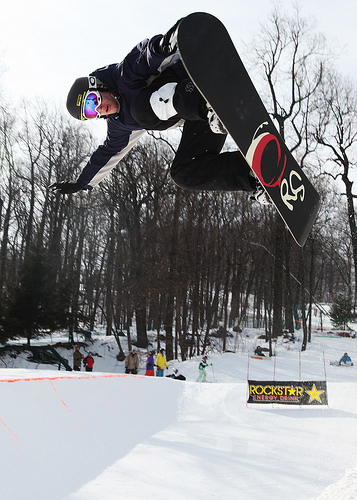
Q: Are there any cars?
A: No, there are no cars.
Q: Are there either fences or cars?
A: No, there are no cars or fences.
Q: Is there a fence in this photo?
A: No, there are no fences.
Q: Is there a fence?
A: No, there are no fences.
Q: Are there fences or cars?
A: No, there are no fences or cars.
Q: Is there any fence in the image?
A: No, there are no fences.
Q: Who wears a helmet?
A: The man wears a helmet.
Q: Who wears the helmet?
A: The man wears a helmet.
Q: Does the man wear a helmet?
A: Yes, the man wears a helmet.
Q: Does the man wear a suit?
A: No, the man wears a helmet.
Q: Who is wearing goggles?
A: The man is wearing goggles.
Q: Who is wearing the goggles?
A: The man is wearing goggles.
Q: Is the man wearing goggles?
A: Yes, the man is wearing goggles.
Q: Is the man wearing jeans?
A: No, the man is wearing goggles.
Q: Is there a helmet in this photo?
A: Yes, there is a helmet.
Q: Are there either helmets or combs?
A: Yes, there is a helmet.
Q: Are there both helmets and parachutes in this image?
A: No, there is a helmet but no parachutes.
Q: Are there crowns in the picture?
A: No, there are no crowns.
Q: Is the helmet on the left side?
A: Yes, the helmet is on the left of the image.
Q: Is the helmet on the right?
A: No, the helmet is on the left of the image.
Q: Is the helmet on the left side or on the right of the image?
A: The helmet is on the left of the image.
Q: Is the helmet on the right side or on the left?
A: The helmet is on the left of the image.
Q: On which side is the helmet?
A: The helmet is on the left of the image.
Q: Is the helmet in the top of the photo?
A: Yes, the helmet is in the top of the image.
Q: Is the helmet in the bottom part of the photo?
A: No, the helmet is in the top of the image.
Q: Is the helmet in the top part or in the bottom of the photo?
A: The helmet is in the top of the image.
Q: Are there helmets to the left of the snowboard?
A: Yes, there is a helmet to the left of the snowboard.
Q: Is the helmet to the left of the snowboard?
A: Yes, the helmet is to the left of the snowboard.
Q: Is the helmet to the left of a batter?
A: No, the helmet is to the left of the snowboard.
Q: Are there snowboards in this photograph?
A: Yes, there is a snowboard.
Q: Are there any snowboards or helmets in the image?
A: Yes, there is a snowboard.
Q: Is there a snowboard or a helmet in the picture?
A: Yes, there is a snowboard.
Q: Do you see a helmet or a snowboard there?
A: Yes, there is a snowboard.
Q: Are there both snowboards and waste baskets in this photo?
A: No, there is a snowboard but no waste baskets.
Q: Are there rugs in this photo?
A: No, there are no rugs.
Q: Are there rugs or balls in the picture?
A: No, there are no rugs or balls.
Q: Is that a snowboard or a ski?
A: That is a snowboard.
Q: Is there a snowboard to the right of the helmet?
A: Yes, there is a snowboard to the right of the helmet.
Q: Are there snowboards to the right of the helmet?
A: Yes, there is a snowboard to the right of the helmet.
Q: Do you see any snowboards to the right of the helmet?
A: Yes, there is a snowboard to the right of the helmet.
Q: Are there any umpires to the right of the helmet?
A: No, there is a snowboard to the right of the helmet.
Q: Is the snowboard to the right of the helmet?
A: Yes, the snowboard is to the right of the helmet.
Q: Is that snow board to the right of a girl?
A: No, the snow board is to the right of the helmet.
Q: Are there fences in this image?
A: No, there are no fences.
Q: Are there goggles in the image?
A: Yes, there are goggles.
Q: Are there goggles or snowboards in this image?
A: Yes, there are goggles.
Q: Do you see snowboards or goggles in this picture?
A: Yes, there are goggles.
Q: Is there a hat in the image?
A: Yes, there is a hat.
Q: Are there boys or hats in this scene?
A: Yes, there is a hat.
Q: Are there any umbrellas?
A: No, there are no umbrellas.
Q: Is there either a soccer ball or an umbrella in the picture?
A: No, there are no umbrellas or soccer balls.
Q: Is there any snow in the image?
A: Yes, there is snow.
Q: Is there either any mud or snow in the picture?
A: Yes, there is snow.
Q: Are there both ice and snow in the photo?
A: No, there is snow but no ice.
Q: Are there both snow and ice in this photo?
A: No, there is snow but no ice.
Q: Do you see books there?
A: No, there are no books.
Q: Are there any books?
A: No, there are no books.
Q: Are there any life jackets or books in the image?
A: No, there are no books or life jackets.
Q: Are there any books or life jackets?
A: No, there are no books or life jackets.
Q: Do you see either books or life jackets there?
A: No, there are no books or life jackets.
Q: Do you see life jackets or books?
A: No, there are no books or life jackets.